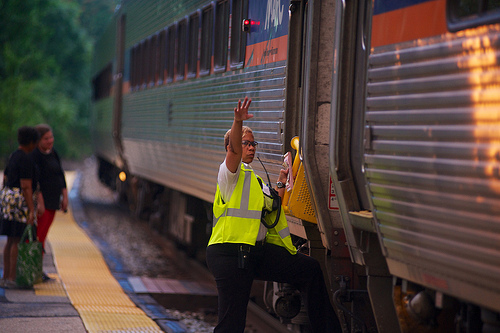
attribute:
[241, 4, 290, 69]
advertising — orange, blue train 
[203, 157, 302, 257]
green vest — reflective 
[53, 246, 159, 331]
platform — bumps, Yellow painted part 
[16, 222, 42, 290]
bag — green 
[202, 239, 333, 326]
pants — black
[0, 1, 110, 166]
green trees — tall, standing , Thick dark green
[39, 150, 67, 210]
shirt — black 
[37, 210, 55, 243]
pants — red 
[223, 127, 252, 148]
hair — cut short 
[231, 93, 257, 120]
hand — her 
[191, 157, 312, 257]
vest — green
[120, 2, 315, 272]
car — silver 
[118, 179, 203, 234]
wheels — Black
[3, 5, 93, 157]
trees —  distance, green 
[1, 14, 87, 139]
tree — background, green leafy 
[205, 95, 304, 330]
worker —  train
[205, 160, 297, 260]
vest — yellow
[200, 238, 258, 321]
pants —  black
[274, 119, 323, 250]
stairs — yellow folded train 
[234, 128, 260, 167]
face — woman's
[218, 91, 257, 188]
hand — woman's right outstretched 